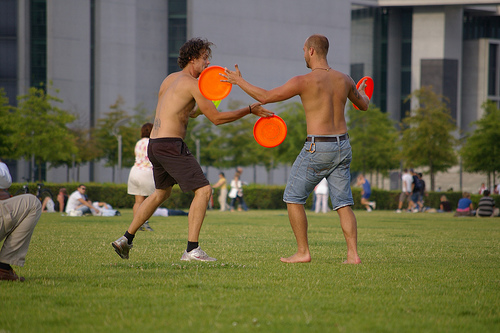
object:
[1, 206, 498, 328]
field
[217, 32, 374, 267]
man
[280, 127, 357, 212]
shorts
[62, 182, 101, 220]
man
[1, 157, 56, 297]
person field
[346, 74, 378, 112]
frisbees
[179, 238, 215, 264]
shoes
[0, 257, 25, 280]
shoes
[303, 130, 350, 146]
dark belt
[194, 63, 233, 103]
frisbee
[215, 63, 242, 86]
hand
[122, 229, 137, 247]
socks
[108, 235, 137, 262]
tennis shoes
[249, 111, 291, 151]
frisbee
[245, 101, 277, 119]
hand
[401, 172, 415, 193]
white shirt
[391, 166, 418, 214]
person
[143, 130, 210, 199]
shorts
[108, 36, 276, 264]
man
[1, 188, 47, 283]
pants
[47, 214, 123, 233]
grass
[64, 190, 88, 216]
shirt